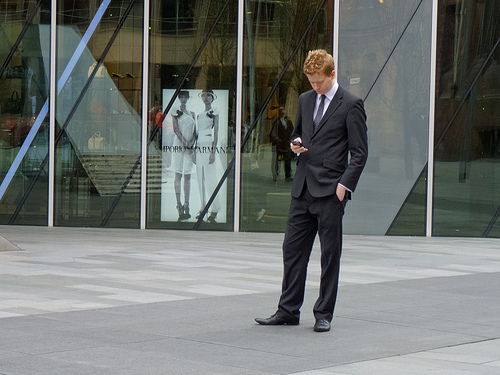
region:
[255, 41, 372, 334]
red haired boy wearing black suit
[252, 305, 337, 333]
black dress shoes on suited man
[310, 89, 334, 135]
black tie on white shoe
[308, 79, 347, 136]
white shirt on man in suit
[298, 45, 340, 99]
short red hair on man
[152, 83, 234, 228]
ad for emporio armani in window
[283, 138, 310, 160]
cell phone being held by man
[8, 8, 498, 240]
set of shop windows near street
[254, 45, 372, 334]
man standing in street looking at phone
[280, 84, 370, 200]
black suit jacket buttoned up on man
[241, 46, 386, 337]
A man is standing.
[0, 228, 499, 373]
Slabs of concrete on the sidewalk.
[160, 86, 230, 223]
A large advertisement in the window.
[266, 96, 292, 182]
A reflection of a person in the window.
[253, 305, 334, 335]
The man is wearing black dress shoes.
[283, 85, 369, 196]
The man is wearing a suit jacket.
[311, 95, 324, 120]
The man is wearing a tie.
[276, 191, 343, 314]
The man is wearing black dress pants.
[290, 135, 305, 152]
The man is holding a phone.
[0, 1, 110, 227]
A blue beam in the window.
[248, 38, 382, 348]
The man is standing.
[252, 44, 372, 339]
The man is looking at a cell phone.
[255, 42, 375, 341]
The man is holding a cell phone.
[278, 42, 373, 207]
The man is looking down.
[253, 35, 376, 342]
The man is wearing a suit.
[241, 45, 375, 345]
The man is wearing shoes.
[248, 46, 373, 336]
The man's shoes are black.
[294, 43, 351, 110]
The man has short hair.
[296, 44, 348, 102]
The man has red hair.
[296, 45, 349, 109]
The man's hair is curly.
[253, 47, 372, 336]
man in a suit looking down at cellphone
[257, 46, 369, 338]
man is texting on a cellphone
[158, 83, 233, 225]
fashion poster in the window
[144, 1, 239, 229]
window to a retail location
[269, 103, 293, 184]
reflection of a man in the window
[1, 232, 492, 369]
gray concrete sidewalk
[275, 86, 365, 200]
black blazer jacket on the man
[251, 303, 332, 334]
black shoes on the man's feet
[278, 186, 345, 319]
black pants on the man's legs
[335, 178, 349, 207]
the man's left hand is in his pocket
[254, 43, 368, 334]
man standing on sidewalk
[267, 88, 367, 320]
black suit of man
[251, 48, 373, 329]
blonde man on street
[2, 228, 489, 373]
gray pavement sidewalk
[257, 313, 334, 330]
black dress shoes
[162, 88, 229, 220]
two womans on a poster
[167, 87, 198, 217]
woman in white dress on poster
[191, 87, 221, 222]
woman with white suit on poster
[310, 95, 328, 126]
blue tie on blonde boy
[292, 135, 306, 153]
little black cellphone